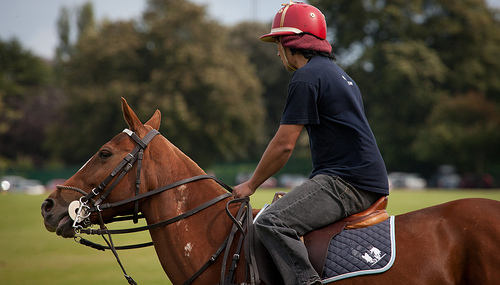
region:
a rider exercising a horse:
[37, 0, 494, 282]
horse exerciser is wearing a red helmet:
[256, 0, 335, 48]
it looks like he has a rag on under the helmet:
[253, 0, 339, 55]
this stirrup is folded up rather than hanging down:
[219, 194, 261, 283]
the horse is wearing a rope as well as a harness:
[51, 178, 143, 283]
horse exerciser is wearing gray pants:
[250, 164, 381, 282]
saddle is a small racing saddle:
[267, 188, 391, 283]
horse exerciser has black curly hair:
[280, 38, 340, 65]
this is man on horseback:
[26, 15, 441, 247]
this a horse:
[61, 107, 250, 274]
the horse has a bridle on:
[65, 102, 234, 264]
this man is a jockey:
[236, 6, 426, 276]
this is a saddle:
[255, 186, 392, 277]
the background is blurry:
[35, 25, 266, 166]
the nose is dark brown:
[21, 195, 81, 241]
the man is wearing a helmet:
[266, 2, 321, 30]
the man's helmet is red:
[255, 5, 358, 60]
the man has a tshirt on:
[275, 51, 451, 253]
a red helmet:
[242, 4, 353, 55]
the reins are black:
[92, 171, 286, 263]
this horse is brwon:
[27, 81, 485, 275]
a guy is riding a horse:
[183, 3, 461, 280]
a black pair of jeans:
[256, 155, 377, 276]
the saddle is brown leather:
[258, 188, 427, 284]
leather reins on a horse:
[72, 97, 279, 275]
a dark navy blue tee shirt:
[276, 45, 414, 222]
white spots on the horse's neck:
[158, 157, 207, 277]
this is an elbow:
[270, 133, 311, 165]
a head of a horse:
[30, 85, 175, 241]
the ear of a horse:
[145, 104, 168, 134]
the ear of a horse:
[116, 91, 145, 136]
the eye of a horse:
[94, 145, 116, 161]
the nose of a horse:
[36, 196, 55, 217]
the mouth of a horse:
[46, 209, 70, 234]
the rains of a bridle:
[69, 171, 246, 249]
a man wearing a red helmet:
[257, 4, 355, 90]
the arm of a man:
[245, 93, 310, 184]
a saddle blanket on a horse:
[331, 217, 400, 280]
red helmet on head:
[257, 4, 337, 43]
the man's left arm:
[238, 67, 306, 207]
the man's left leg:
[257, 174, 357, 282]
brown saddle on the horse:
[338, 198, 401, 238]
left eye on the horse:
[100, 146, 116, 165]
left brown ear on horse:
[114, 95, 146, 129]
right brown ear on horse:
[144, 98, 167, 132]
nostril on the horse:
[32, 196, 64, 211]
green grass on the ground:
[4, 241, 72, 283]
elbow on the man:
[275, 141, 298, 158]